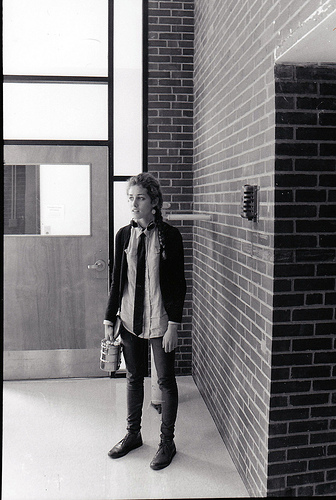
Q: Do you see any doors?
A: Yes, there is a door.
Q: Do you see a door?
A: Yes, there is a door.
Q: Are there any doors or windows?
A: Yes, there is a door.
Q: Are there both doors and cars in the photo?
A: No, there is a door but no cars.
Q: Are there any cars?
A: No, there are no cars.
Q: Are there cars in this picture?
A: No, there are no cars.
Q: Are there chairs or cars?
A: No, there are no cars or chairs.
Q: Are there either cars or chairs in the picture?
A: No, there are no cars or chairs.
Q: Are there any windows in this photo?
A: Yes, there is a window.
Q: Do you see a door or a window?
A: Yes, there is a window.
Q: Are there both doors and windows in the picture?
A: Yes, there are both a window and a door.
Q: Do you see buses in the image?
A: No, there are no buses.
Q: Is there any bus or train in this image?
A: No, there are no buses or trains.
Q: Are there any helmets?
A: No, there are no helmets.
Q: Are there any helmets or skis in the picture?
A: No, there are no helmets or skis.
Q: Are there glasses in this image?
A: No, there are no glasses.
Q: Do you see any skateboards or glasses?
A: No, there are no glasses or skateboards.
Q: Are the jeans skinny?
A: Yes, the jeans are skinny.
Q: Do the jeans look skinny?
A: Yes, the jeans are skinny.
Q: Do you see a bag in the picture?
A: No, there are no bags.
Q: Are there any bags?
A: No, there are no bags.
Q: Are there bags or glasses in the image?
A: No, there are no bags or glasses.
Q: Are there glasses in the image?
A: No, there are no glasses.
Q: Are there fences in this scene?
A: No, there are no fences.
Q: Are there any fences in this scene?
A: No, there are no fences.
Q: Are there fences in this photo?
A: No, there are no fences.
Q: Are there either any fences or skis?
A: No, there are no fences or skis.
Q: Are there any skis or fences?
A: No, there are no fences or skis.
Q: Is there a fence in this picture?
A: No, there are no fences.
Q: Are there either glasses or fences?
A: No, there are no fences or glasses.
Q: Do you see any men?
A: No, there are no men.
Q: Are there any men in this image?
A: No, there are no men.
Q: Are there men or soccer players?
A: No, there are no men or soccer players.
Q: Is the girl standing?
A: Yes, the girl is standing.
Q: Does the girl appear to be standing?
A: Yes, the girl is standing.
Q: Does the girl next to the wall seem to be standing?
A: Yes, the girl is standing.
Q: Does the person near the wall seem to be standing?
A: Yes, the girl is standing.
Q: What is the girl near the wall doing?
A: The girl is standing.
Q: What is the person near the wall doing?
A: The girl is standing.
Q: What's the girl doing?
A: The girl is standing.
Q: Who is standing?
A: The girl is standing.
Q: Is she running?
A: No, the girl is standing.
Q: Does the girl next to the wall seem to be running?
A: No, the girl is standing.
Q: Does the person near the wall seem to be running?
A: No, the girl is standing.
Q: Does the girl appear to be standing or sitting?
A: The girl is standing.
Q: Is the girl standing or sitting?
A: The girl is standing.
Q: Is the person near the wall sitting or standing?
A: The girl is standing.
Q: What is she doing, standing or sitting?
A: The girl is standing.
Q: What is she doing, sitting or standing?
A: The girl is standing.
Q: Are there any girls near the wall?
A: Yes, there is a girl near the wall.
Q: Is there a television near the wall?
A: No, there is a girl near the wall.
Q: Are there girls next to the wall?
A: Yes, there is a girl next to the wall.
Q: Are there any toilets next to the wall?
A: No, there is a girl next to the wall.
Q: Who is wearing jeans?
A: The girl is wearing jeans.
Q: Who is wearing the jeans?
A: The girl is wearing jeans.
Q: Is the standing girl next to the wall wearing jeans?
A: Yes, the girl is wearing jeans.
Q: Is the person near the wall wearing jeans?
A: Yes, the girl is wearing jeans.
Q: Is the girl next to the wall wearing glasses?
A: No, the girl is wearing jeans.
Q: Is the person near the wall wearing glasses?
A: No, the girl is wearing jeans.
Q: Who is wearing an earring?
A: The girl is wearing an earring.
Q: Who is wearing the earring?
A: The girl is wearing an earring.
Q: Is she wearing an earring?
A: Yes, the girl is wearing an earring.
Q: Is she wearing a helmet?
A: No, the girl is wearing an earring.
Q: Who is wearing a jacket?
A: The girl is wearing a jacket.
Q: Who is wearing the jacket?
A: The girl is wearing a jacket.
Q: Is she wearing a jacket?
A: Yes, the girl is wearing a jacket.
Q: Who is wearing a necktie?
A: The girl is wearing a necktie.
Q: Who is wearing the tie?
A: The girl is wearing a necktie.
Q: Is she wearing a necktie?
A: Yes, the girl is wearing a necktie.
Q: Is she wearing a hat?
A: No, the girl is wearing a necktie.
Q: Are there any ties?
A: Yes, there is a tie.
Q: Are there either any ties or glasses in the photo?
A: Yes, there is a tie.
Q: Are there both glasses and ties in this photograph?
A: No, there is a tie but no glasses.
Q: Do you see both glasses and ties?
A: No, there is a tie but no glasses.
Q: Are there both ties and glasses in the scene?
A: No, there is a tie but no glasses.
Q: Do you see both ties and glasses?
A: No, there is a tie but no glasses.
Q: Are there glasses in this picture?
A: No, there are no glasses.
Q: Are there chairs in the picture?
A: No, there are no chairs.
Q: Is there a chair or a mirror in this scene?
A: No, there are no chairs or mirrors.